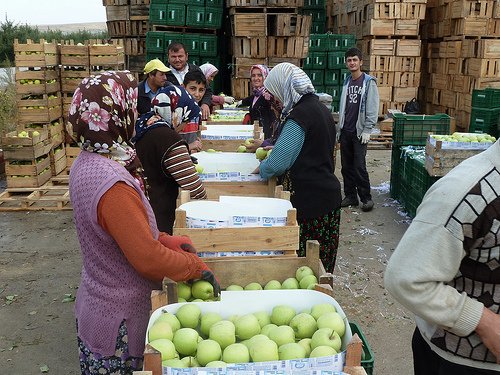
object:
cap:
[142, 58, 172, 75]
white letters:
[350, 86, 355, 93]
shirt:
[342, 73, 364, 134]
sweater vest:
[65, 150, 157, 358]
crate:
[67, 144, 82, 171]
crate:
[89, 39, 126, 67]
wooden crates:
[475, 39, 500, 60]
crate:
[62, 92, 77, 120]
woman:
[63, 69, 218, 375]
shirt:
[101, 181, 199, 282]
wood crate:
[15, 38, 55, 69]